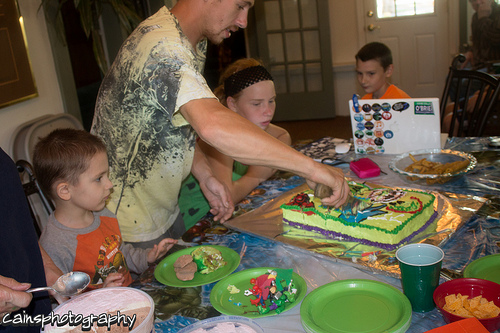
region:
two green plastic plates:
[151, 241, 309, 319]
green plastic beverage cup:
[393, 241, 446, 312]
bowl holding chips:
[432, 275, 497, 332]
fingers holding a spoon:
[0, 269, 92, 319]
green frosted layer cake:
[278, 175, 441, 248]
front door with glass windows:
[358, 0, 464, 103]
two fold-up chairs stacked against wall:
[8, 110, 88, 232]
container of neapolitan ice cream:
[37, 286, 156, 331]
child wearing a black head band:
[216, 61, 295, 204]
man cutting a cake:
[88, 0, 443, 252]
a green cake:
[282, 165, 430, 252]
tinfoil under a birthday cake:
[215, 165, 493, 266]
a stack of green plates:
[306, 279, 404, 331]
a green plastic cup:
[394, 234, 446, 303]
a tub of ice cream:
[47, 279, 162, 331]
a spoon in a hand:
[0, 263, 97, 311]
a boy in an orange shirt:
[345, 40, 416, 107]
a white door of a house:
[358, 0, 469, 105]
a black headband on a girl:
[222, 58, 279, 99]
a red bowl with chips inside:
[432, 275, 498, 320]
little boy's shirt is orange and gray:
[35, 196, 140, 285]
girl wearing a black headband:
[216, 61, 301, 121]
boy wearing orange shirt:
[341, 74, 431, 123]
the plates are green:
[138, 227, 412, 332]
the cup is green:
[386, 240, 458, 300]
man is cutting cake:
[136, 0, 435, 245]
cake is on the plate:
[166, 240, 291, 332]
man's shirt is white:
[72, 0, 252, 277]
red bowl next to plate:
[428, 273, 498, 326]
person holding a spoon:
[3, 264, 118, 331]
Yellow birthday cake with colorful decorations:
[354, 181, 435, 247]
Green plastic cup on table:
[394, 244, 442, 313]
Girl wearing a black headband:
[219, 63, 285, 133]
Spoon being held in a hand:
[14, 263, 96, 316]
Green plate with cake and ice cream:
[156, 242, 231, 282]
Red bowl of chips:
[437, 274, 498, 328]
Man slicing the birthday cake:
[128, 2, 380, 239]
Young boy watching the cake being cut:
[33, 131, 148, 285]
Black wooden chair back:
[440, 53, 496, 154]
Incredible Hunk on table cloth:
[147, 277, 214, 325]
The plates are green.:
[299, 271, 415, 331]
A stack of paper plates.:
[296, 276, 416, 331]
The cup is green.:
[388, 238, 447, 317]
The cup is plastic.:
[393, 240, 441, 317]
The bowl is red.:
[431, 271, 499, 330]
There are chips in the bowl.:
[431, 275, 499, 325]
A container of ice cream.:
[31, 275, 157, 331]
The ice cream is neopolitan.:
[40, 282, 155, 331]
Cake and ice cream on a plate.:
[146, 236, 243, 299]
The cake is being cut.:
[257, 141, 446, 258]